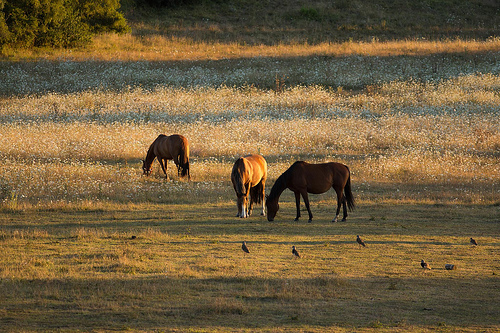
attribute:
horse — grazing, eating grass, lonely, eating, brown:
[134, 130, 192, 186]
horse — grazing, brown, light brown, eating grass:
[229, 150, 271, 218]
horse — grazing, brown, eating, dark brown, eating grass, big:
[267, 155, 356, 225]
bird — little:
[239, 239, 250, 255]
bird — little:
[352, 233, 367, 248]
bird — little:
[465, 236, 480, 249]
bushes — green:
[3, 3, 124, 44]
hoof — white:
[331, 212, 340, 222]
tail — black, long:
[344, 167, 356, 216]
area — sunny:
[110, 34, 499, 54]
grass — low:
[1, 215, 496, 331]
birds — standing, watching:
[240, 235, 480, 268]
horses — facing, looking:
[138, 122, 358, 226]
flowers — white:
[0, 70, 499, 179]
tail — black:
[347, 166, 355, 209]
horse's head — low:
[235, 196, 253, 222]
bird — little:
[289, 242, 302, 257]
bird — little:
[414, 259, 434, 272]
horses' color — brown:
[267, 151, 356, 225]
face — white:
[237, 194, 248, 217]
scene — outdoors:
[1, 4, 499, 328]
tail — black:
[182, 140, 189, 178]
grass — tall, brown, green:
[3, 56, 499, 185]